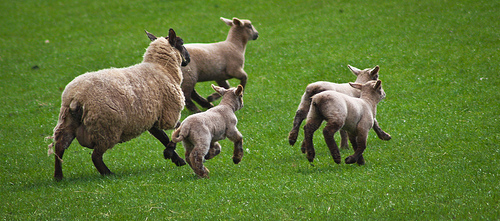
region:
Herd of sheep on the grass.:
[40, 12, 401, 190]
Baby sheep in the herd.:
[160, 57, 400, 182]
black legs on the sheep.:
[296, 110, 371, 170]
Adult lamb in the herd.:
[40, 26, 190, 181]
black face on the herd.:
[145, 25, 191, 65]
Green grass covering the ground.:
[0, 0, 495, 215]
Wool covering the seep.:
[48, 31, 193, 175]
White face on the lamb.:
[217, 10, 269, 47]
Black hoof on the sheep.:
[170, 153, 187, 170]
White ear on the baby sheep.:
[345, 58, 364, 78]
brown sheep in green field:
[301, 73, 391, 147]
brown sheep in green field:
[270, 29, 380, 173]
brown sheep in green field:
[137, 81, 261, 183]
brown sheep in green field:
[50, 26, 264, 194]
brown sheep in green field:
[192, 12, 267, 64]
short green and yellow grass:
[248, 159, 325, 216]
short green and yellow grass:
[377, 169, 424, 190]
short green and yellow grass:
[220, 161, 285, 206]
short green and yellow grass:
[402, 43, 454, 84]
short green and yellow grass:
[357, 13, 425, 35]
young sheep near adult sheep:
[163, 82, 256, 178]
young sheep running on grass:
[163, 78, 250, 181]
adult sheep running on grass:
[42, 28, 193, 185]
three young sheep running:
[155, 60, 394, 178]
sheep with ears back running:
[177, 13, 262, 105]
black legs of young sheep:
[298, 117, 373, 172]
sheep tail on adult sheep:
[64, 96, 82, 116]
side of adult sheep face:
[165, 25, 197, 70]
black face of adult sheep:
[163, 27, 193, 69]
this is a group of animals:
[51, 16, 416, 186]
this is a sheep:
[31, 10, 207, 167]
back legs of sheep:
[40, 124, 125, 199]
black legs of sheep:
[45, 122, 131, 181]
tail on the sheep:
[55, 82, 108, 128]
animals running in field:
[42, 2, 437, 186]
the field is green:
[33, 10, 491, 207]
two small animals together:
[277, 41, 412, 171]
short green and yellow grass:
[14, 11, 52, 45]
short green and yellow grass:
[430, 178, 475, 219]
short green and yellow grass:
[401, 68, 446, 105]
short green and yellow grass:
[398, 16, 450, 51]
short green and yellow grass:
[130, 175, 208, 219]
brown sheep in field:
[51, 13, 185, 184]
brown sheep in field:
[165, 79, 267, 171]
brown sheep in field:
[294, 55, 404, 165]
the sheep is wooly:
[71, 42, 181, 169]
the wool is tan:
[77, 64, 174, 126]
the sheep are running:
[71, 12, 388, 174]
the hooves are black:
[302, 142, 369, 163]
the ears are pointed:
[220, 11, 237, 27]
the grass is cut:
[250, 0, 491, 98]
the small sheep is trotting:
[184, 81, 249, 181]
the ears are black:
[142, 25, 178, 46]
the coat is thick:
[75, 55, 180, 146]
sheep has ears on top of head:
[348, 59, 386, 78]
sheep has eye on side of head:
[246, 18, 258, 29]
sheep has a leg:
[324, 117, 348, 166]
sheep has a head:
[227, 8, 269, 45]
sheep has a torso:
[176, 103, 241, 147]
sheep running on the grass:
[280, 68, 412, 168]